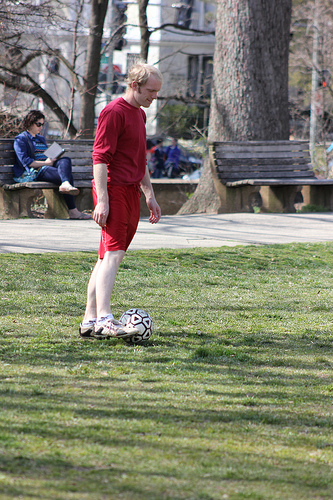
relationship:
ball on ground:
[111, 310, 153, 341] [170, 301, 243, 358]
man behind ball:
[74, 60, 165, 340] [118, 305, 153, 341]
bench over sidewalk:
[219, 140, 283, 167] [188, 224, 250, 241]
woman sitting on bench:
[13, 109, 89, 218] [1, 136, 94, 217]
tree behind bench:
[176, 0, 291, 216] [211, 137, 333, 189]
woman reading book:
[13, 109, 89, 218] [43, 141, 66, 160]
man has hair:
[74, 60, 165, 335] [128, 62, 162, 94]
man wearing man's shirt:
[74, 60, 165, 335] [89, 98, 157, 192]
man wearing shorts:
[74, 60, 165, 335] [90, 175, 142, 256]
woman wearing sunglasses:
[13, 109, 89, 218] [28, 120, 46, 127]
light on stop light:
[320, 79, 328, 89] [314, 68, 328, 90]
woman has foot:
[13, 109, 89, 218] [57, 180, 78, 194]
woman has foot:
[13, 109, 89, 218] [67, 209, 91, 219]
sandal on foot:
[56, 186, 77, 194] [57, 180, 78, 194]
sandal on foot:
[67, 211, 93, 219] [67, 209, 91, 219]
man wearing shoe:
[74, 60, 165, 335] [93, 316, 132, 339]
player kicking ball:
[78, 61, 162, 338] [118, 305, 153, 341]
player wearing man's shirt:
[78, 61, 162, 338] [89, 98, 157, 192]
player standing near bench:
[78, 61, 162, 338] [1, 136, 94, 217]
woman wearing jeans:
[13, 109, 89, 218] [38, 156, 76, 208]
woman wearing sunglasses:
[13, 109, 89, 218] [33, 121, 44, 128]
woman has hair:
[13, 109, 89, 218] [21, 109, 45, 128]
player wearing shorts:
[78, 61, 162, 338] [90, 175, 142, 256]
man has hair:
[74, 60, 165, 335] [128, 62, 162, 80]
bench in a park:
[211, 137, 333, 189] [0, 0, 325, 497]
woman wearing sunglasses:
[13, 109, 89, 218] [28, 118, 46, 127]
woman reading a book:
[13, 109, 89, 218] [42, 138, 71, 174]